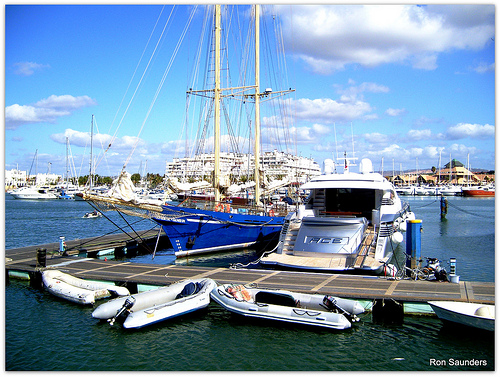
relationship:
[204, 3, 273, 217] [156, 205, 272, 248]
masts are attached to boat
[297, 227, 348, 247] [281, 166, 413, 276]
word attached to boat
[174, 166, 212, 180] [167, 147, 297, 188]
wall attached to building